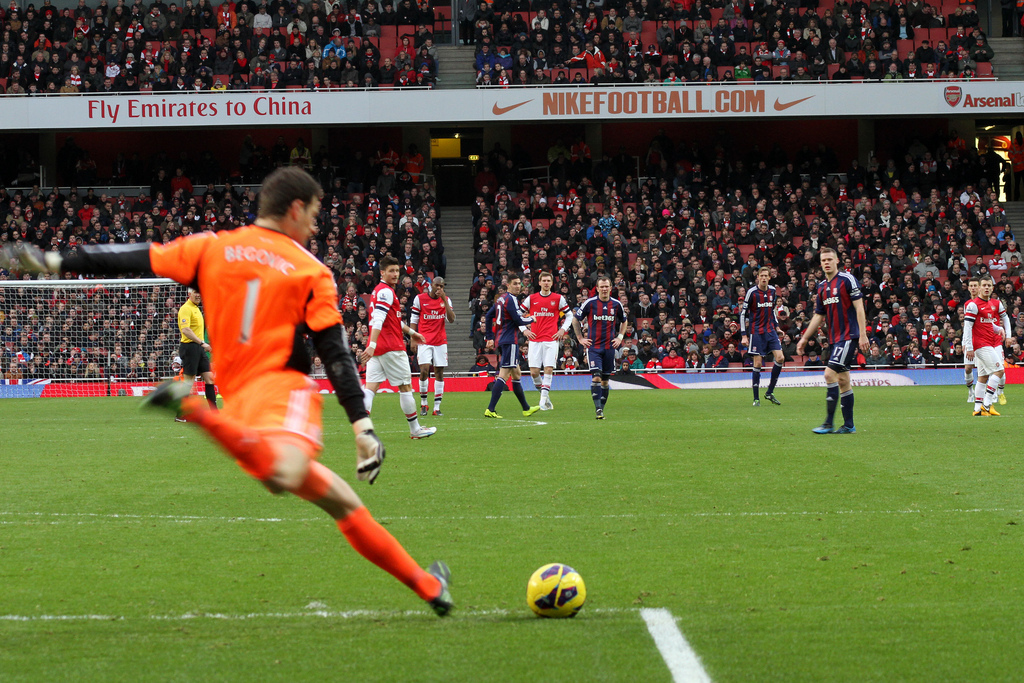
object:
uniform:
[58, 221, 438, 608]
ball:
[523, 564, 584, 619]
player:
[796, 248, 872, 434]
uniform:
[816, 272, 863, 373]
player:
[740, 268, 786, 406]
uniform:
[740, 285, 783, 355]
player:
[572, 276, 629, 419]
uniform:
[573, 296, 628, 373]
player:
[485, 275, 542, 419]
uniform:
[485, 292, 534, 369]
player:
[518, 272, 572, 410]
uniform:
[518, 292, 575, 368]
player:
[410, 276, 456, 416]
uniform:
[410, 292, 457, 367]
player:
[359, 257, 438, 439]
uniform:
[364, 282, 411, 386]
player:
[961, 276, 1005, 417]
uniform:
[963, 296, 1001, 377]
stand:
[5, 116, 1024, 401]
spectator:
[662, 349, 686, 374]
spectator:
[421, 240, 441, 269]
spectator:
[532, 228, 551, 247]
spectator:
[890, 180, 907, 203]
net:
[0, 276, 203, 399]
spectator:
[217, 3, 237, 30]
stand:
[5, 0, 1024, 96]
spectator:
[395, 35, 417, 58]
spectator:
[564, 41, 607, 70]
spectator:
[140, 42, 159, 63]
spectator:
[677, 42, 694, 65]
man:
[0, 166, 455, 618]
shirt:
[176, 298, 203, 343]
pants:
[180, 342, 212, 376]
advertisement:
[0, 80, 1022, 130]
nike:
[493, 89, 816, 115]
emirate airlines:
[88, 96, 312, 123]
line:
[640, 607, 712, 682]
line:
[3, 508, 1022, 523]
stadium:
[0, 0, 1022, 399]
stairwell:
[440, 207, 475, 377]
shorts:
[365, 350, 411, 386]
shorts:
[417, 343, 449, 367]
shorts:
[528, 340, 560, 368]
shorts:
[974, 346, 1006, 378]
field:
[0, 388, 1024, 683]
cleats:
[139, 380, 193, 412]